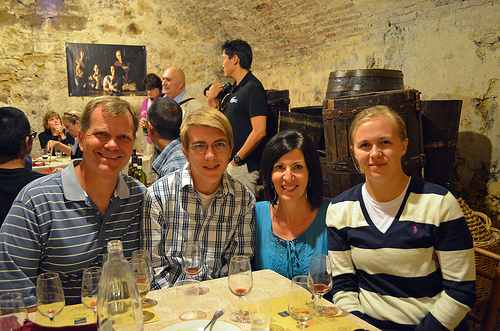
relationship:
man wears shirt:
[12, 117, 157, 320] [19, 171, 140, 246]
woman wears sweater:
[239, 120, 344, 290] [251, 190, 336, 290]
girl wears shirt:
[323, 104, 478, 329] [331, 184, 471, 328]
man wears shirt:
[206, 38, 267, 196] [218, 69, 268, 173]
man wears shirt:
[0, 105, 48, 222] [0, 165, 47, 226]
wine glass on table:
[34, 270, 66, 330] [4, 257, 381, 329]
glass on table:
[228, 256, 254, 323] [31, 252, 383, 328]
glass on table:
[228, 256, 254, 323] [49, 253, 372, 329]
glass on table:
[288, 275, 317, 330] [23, 272, 405, 327]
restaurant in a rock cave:
[3, 0, 499, 330] [0, 3, 499, 328]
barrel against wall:
[323, 70, 426, 199] [2, 1, 497, 225]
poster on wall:
[63, 40, 150, 97] [0, 7, 218, 107]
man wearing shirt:
[0, 96, 147, 313] [7, 165, 190, 292]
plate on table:
[158, 319, 247, 330] [5, 268, 381, 328]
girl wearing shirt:
[325, 104, 476, 329] [326, 176, 478, 329]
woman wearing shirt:
[254, 129, 335, 291] [253, 197, 328, 274]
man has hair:
[156, 78, 241, 273] [183, 106, 240, 136]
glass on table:
[228, 256, 254, 323] [247, 258, 298, 310]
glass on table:
[288, 275, 317, 330] [5, 268, 381, 328]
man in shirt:
[206, 38, 267, 196] [219, 79, 272, 160]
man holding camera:
[165, 31, 313, 165] [194, 63, 245, 91]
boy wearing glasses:
[139, 107, 256, 290] [182, 136, 232, 151]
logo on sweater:
[410, 219, 422, 234] [320, 173, 480, 329]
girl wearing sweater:
[325, 104, 476, 329] [328, 180, 478, 328]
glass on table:
[227, 243, 257, 327] [30, 263, 367, 329]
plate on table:
[158, 309, 246, 329] [48, 174, 357, 329]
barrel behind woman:
[320, 71, 428, 183] [322, 114, 467, 329]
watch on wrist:
[231, 154, 242, 165] [233, 149, 248, 169]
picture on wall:
[65, 42, 146, 97] [2, 0, 234, 164]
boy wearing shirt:
[139, 107, 256, 290] [136, 165, 260, 292]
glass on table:
[223, 250, 336, 317] [5, 268, 381, 328]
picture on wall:
[64, 40, 146, 97] [2, 2, 224, 112]